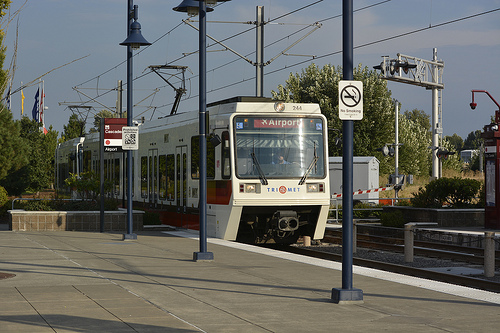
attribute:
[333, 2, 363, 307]
pole — dark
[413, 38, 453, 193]
pole — tall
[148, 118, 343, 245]
train — white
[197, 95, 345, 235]
train — white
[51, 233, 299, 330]
platform — gray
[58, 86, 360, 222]
train — white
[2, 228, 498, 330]
pavement — brown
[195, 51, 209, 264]
poles — telephone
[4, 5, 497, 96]
sky — blue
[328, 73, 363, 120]
sign — saying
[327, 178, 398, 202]
gate — automatic, stopping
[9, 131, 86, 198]
leaves — green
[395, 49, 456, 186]
light post — silver